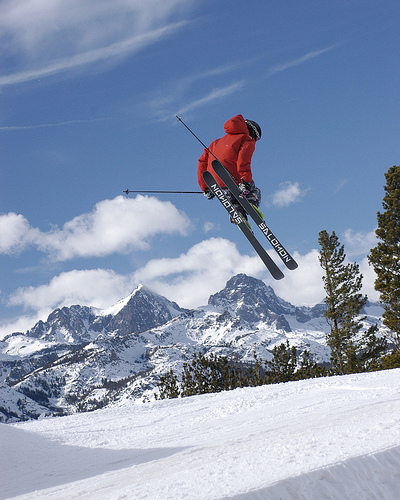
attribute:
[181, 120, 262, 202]
coat — red, hooded, winter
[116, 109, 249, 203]
poles — ski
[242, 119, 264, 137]
helmet — black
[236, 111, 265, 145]
head — man's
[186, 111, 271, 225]
person — athletic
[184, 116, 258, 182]
jacket — orange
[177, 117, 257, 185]
jacket — red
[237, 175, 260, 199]
hand — glove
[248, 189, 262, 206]
hand — glove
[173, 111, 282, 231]
skier — jumping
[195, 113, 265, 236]
skier — part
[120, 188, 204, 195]
pole — skiers, athletic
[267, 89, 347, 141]
sky — blue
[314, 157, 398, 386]
trees — tall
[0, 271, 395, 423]
mountains — in background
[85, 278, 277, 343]
hill — ski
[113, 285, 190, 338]
hill — ski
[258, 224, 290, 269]
label — salomon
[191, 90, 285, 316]
jump — high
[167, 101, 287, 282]
skier — jumping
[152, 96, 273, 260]
ski — person's, athlectic, part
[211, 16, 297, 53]
sky — clear, blue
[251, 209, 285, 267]
salomon — word